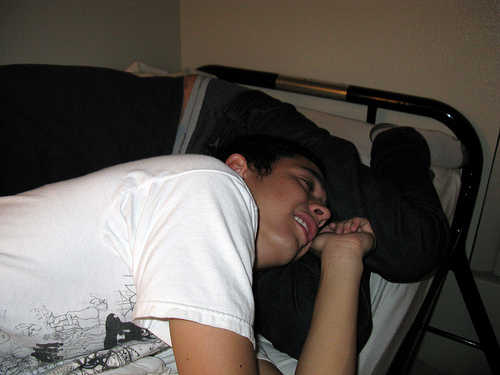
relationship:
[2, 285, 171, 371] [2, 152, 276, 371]
design on shirt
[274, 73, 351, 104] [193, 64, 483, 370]
metal on headboard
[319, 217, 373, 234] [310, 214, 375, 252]
finger on hand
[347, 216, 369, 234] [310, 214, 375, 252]
finger on hand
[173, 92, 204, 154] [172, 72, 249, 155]
elastic on boy's underwear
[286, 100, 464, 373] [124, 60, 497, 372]
sheet on bed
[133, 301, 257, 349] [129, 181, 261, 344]
edge on sleeve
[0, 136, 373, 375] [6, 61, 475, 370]
boy sleeping on bed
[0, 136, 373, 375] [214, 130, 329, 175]
boy with hair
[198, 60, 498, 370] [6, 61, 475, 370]
metal frame of bed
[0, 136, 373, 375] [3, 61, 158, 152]
boy wearing blackshirt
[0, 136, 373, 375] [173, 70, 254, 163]
boy wearing gray underwear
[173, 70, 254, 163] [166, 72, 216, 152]
gray underwear with border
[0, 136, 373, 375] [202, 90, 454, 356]
boy wearing pants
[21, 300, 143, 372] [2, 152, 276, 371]
drawing on shirt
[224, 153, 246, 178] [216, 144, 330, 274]
ear on head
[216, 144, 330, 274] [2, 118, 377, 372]
head of boy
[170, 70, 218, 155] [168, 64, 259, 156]
elastic band on boy's underwear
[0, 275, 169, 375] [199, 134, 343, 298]
design on boy's shirt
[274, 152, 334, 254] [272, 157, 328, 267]
mouth face on face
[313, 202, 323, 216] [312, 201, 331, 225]
nostril on nose